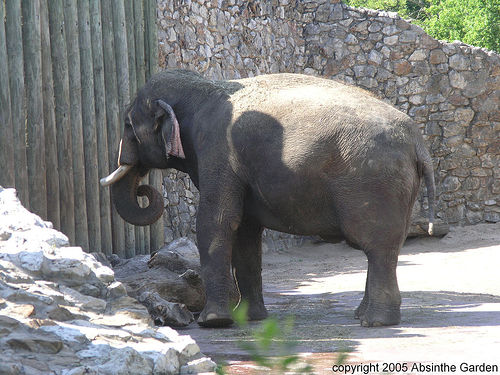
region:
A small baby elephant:
[102, 62, 442, 329]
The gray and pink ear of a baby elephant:
[143, 95, 193, 165]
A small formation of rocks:
[0, 194, 220, 374]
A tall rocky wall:
[259, 0, 495, 224]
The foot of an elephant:
[192, 305, 237, 330]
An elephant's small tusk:
[90, 155, 141, 192]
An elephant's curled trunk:
[103, 163, 174, 228]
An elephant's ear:
[412, 155, 445, 236]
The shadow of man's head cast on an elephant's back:
[222, 105, 313, 180]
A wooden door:
[1, 0, 137, 235]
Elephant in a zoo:
[90, 41, 450, 341]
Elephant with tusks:
[85, 45, 445, 335]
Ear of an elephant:
[142, 95, 187, 161]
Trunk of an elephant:
[106, 180, 178, 230]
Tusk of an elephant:
[90, 151, 135, 186]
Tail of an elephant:
[400, 141, 457, 236]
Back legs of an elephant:
[350, 256, 415, 331]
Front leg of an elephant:
[190, 235, 236, 331]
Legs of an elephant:
[176, 227, 416, 332]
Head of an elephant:
[95, 42, 188, 227]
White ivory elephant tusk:
[90, 153, 140, 197]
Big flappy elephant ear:
[149, 93, 191, 162]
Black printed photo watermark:
[330, 355, 498, 373]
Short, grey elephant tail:
[407, 136, 446, 237]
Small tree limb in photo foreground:
[202, 298, 356, 374]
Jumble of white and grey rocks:
[1, 174, 147, 371]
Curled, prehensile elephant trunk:
[105, 173, 169, 236]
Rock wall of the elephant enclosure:
[151, 3, 493, 246]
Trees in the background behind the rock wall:
[353, 0, 498, 52]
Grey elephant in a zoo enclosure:
[87, 52, 444, 323]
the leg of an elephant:
[196, 185, 246, 300]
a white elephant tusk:
[96, 160, 138, 191]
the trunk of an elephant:
[106, 155, 169, 228]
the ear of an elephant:
[140, 89, 195, 171]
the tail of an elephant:
[411, 145, 447, 247]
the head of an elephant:
[113, 64, 211, 180]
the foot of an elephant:
[188, 296, 252, 331]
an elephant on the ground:
[98, 61, 452, 338]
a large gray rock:
[2, 182, 218, 373]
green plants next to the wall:
[342, 0, 499, 56]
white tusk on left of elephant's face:
[97, 131, 128, 197]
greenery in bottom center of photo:
[242, 305, 296, 370]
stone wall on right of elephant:
[305, 9, 415, 82]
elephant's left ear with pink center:
[150, 102, 203, 174]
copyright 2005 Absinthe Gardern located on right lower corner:
[331, 351, 498, 373]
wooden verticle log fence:
[46, 29, 139, 115]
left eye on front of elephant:
[118, 114, 141, 135]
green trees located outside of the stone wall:
[447, 3, 497, 44]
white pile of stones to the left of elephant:
[14, 242, 111, 369]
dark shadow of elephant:
[287, 279, 497, 350]